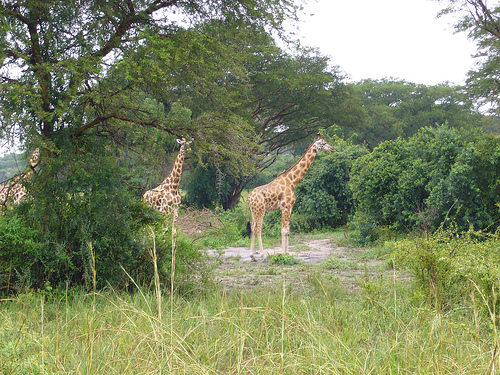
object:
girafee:
[248, 135, 332, 258]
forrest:
[0, 29, 500, 293]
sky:
[343, 3, 434, 71]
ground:
[231, 254, 288, 283]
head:
[314, 139, 336, 153]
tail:
[246, 196, 252, 236]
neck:
[289, 149, 319, 189]